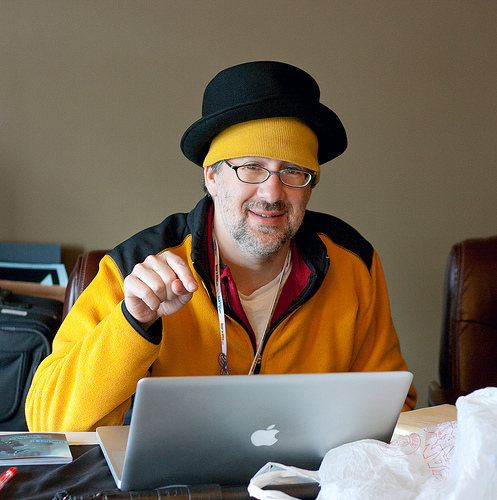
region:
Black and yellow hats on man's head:
[176, 49, 373, 285]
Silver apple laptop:
[90, 363, 412, 499]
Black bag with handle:
[0, 283, 64, 433]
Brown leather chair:
[428, 206, 494, 398]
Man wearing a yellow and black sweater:
[21, 76, 426, 445]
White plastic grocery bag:
[247, 390, 496, 498]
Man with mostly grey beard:
[200, 120, 315, 272]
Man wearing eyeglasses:
[212, 123, 322, 273]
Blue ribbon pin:
[210, 336, 234, 387]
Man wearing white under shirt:
[109, 80, 434, 395]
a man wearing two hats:
[27, 59, 416, 421]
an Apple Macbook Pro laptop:
[96, 374, 412, 485]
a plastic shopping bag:
[248, 381, 492, 495]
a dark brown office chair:
[441, 236, 493, 392]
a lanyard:
[209, 216, 292, 375]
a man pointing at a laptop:
[25, 59, 419, 488]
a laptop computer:
[96, 374, 412, 484]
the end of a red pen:
[0, 465, 19, 491]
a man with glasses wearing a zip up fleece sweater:
[23, 60, 419, 432]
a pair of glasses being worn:
[220, 157, 317, 188]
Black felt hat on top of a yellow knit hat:
[173, 58, 358, 173]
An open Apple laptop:
[91, 367, 439, 476]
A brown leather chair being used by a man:
[58, 225, 129, 313]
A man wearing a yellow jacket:
[59, 202, 304, 363]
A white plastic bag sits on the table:
[294, 406, 490, 492]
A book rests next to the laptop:
[5, 423, 77, 474]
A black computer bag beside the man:
[2, 271, 73, 426]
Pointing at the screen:
[91, 228, 241, 353]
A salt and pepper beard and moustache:
[222, 191, 306, 267]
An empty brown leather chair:
[440, 228, 494, 287]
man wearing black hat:
[153, 47, 359, 274]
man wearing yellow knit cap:
[191, 104, 352, 192]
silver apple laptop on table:
[106, 356, 414, 488]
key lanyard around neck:
[198, 226, 290, 388]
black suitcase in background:
[3, 284, 56, 427]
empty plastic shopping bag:
[291, 408, 489, 495]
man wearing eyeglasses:
[211, 148, 319, 200]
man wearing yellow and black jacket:
[63, 202, 459, 435]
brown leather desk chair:
[423, 225, 496, 394]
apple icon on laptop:
[227, 404, 289, 467]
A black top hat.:
[161, 65, 387, 138]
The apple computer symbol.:
[212, 405, 316, 480]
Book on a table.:
[0, 418, 78, 479]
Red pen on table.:
[0, 448, 34, 493]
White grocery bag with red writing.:
[355, 374, 493, 496]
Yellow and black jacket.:
[2, 237, 371, 418]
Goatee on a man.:
[216, 205, 299, 273]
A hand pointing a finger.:
[100, 227, 199, 391]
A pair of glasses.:
[199, 164, 315, 213]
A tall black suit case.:
[1, 288, 67, 448]